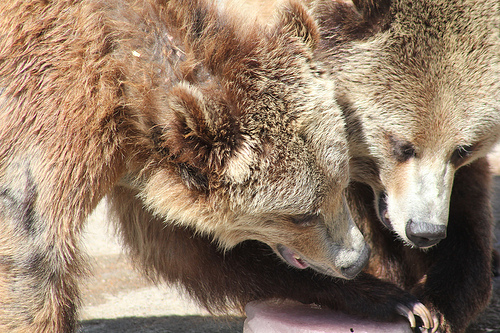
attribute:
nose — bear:
[402, 216, 449, 248]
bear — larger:
[4, 5, 376, 330]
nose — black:
[339, 234, 375, 279]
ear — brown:
[157, 78, 229, 145]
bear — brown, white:
[322, 7, 498, 327]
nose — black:
[401, 218, 448, 248]